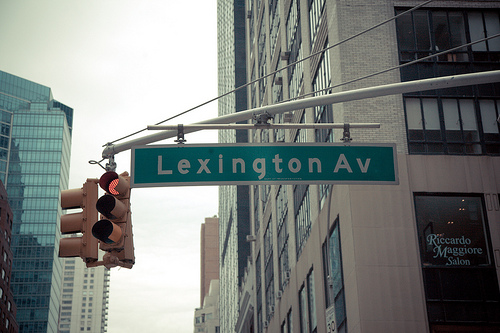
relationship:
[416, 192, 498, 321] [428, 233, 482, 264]
window says riccardo maggiore sa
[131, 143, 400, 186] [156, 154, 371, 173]
sign says lexington avenue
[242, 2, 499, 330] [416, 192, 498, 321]
building has a window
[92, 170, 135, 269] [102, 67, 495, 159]
signal on a pole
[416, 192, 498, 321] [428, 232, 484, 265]
window has decal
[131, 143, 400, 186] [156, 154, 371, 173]
sign for lexington avenue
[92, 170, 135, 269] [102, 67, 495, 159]
signal hanging on a pole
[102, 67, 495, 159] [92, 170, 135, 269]
pole has a signal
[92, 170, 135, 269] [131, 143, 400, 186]
signal next to a sign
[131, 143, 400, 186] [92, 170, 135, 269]
sign next to a signal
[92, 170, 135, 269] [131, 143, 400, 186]
signal by a sign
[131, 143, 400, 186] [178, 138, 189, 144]
sign has a bracket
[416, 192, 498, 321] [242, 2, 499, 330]
window in a building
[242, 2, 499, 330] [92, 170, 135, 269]
building near a signal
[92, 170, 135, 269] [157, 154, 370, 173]
signal has a street name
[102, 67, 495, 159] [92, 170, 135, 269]
pole beside a signal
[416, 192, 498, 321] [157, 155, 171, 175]
window has writing